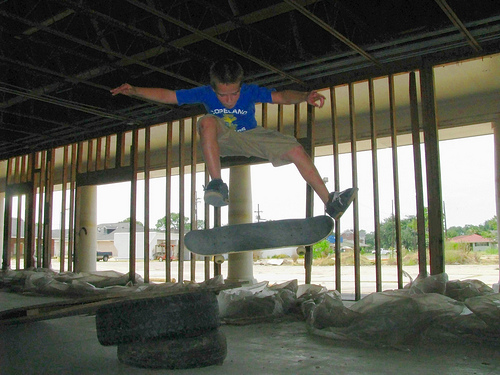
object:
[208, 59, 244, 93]
hair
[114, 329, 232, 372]
tires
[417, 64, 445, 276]
stud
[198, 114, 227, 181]
leg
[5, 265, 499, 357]
sheeting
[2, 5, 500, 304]
building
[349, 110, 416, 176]
ground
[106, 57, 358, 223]
boy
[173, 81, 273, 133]
t-shirt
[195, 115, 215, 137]
knee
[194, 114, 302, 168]
shorts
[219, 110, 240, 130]
horse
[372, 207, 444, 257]
trees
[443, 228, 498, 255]
building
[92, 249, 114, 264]
pickup truck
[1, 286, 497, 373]
floor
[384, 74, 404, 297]
wall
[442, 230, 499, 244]
roof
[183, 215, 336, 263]
skateboard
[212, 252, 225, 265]
wheel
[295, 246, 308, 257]
wheel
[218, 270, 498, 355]
plastic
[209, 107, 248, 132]
designs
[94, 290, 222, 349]
tire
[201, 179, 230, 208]
shoe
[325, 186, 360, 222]
shoe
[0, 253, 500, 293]
parking lot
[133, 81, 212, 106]
arms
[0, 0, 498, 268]
background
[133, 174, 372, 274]
mid air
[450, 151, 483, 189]
air